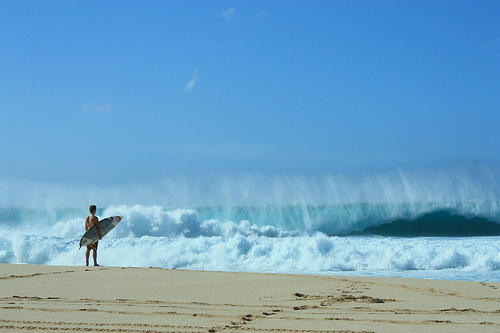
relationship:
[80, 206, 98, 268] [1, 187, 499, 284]
boy standing by ocean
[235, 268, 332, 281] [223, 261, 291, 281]
line of dirt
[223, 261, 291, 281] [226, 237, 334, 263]
dirt meets water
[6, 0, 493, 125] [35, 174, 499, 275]
skies above water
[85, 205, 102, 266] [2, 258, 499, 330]
boy standing on beach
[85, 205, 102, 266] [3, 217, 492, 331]
boy on beach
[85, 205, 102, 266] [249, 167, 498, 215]
boy looking at waves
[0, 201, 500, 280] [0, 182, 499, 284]
ocean of wave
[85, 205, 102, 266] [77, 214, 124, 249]
boy holding surfboard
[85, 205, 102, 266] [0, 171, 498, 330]
boy on beach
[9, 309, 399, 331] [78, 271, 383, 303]
tracks in sand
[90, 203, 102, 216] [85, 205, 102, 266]
head of boy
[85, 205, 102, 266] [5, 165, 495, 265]
boy in front of ocean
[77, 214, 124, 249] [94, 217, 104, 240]
surfboard under arm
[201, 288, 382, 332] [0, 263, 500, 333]
footsteps on ground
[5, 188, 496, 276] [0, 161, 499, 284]
waves in ocean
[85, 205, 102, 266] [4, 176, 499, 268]
boy facing ocean